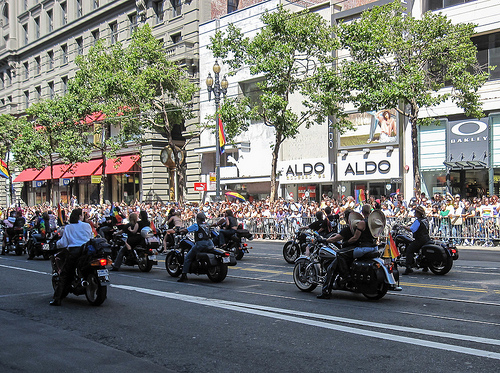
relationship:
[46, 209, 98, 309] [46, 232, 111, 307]
motorcyclist on motorcycle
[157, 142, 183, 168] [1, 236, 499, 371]
clock overlooking street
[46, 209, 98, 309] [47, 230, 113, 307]
motorcyclist riding a bike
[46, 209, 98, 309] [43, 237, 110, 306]
motorcyclist riding motorcycle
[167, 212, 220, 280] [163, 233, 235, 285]
biker riding motorcycle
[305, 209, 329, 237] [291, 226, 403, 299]
person riding motorcycle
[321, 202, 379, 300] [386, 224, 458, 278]
person riding motorcycle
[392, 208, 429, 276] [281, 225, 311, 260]
biker riding motorcycle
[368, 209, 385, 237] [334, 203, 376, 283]
hat behind woman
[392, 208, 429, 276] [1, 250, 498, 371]
biker on street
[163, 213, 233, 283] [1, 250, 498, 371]
motorist on street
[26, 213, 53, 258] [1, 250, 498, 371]
motorist on street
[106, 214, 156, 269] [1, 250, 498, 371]
motorist on street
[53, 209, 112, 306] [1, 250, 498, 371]
motorist on street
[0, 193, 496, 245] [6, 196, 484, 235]
crowd on people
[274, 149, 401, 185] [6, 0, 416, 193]
signs on buildings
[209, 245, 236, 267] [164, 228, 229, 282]
light on bike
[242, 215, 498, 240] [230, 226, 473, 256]
fence by side walk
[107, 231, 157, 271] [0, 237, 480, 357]
motorcycle on street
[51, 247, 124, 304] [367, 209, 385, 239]
bike with hat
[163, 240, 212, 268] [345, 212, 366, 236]
bike with hat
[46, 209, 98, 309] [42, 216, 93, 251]
motorcyclist in a shirt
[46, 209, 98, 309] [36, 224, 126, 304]
motorcyclist on a motorcycle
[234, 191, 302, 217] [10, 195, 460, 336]
spectators watching parade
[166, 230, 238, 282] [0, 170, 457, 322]
motorcyclist in a parade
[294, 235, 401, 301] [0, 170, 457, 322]
motorcyclist in a parade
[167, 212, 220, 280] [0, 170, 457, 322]
biker in a parade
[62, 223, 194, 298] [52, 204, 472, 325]
motorcyclist in a parade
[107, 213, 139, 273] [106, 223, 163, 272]
motorcyclist on a motorcycle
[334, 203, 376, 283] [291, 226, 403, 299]
woman on a motorcycle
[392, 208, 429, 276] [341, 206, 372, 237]
biker wearing hat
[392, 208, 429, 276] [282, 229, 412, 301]
biker on a motorcycle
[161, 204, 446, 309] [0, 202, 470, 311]
people riding motorcycle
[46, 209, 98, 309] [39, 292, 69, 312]
motorcyclist wearing shoes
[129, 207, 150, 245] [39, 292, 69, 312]
woman wearing shoes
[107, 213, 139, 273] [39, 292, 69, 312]
motorcyclist wearing shoes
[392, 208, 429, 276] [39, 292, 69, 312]
biker wearing shoes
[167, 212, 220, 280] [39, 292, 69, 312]
biker wearing shoes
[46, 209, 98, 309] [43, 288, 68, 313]
motorcyclist wearing shoes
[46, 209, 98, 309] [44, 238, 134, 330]
motorcyclist wearing pants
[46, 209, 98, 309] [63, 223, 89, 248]
motorcyclist wearing shirt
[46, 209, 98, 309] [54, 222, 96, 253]
motorcyclist wearing shirt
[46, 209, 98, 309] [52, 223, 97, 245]
motorcyclist wearing shirt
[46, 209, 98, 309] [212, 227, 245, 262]
motorcyclist on motorcycle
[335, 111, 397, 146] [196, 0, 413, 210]
print on building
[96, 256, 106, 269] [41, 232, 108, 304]
light on motorcycle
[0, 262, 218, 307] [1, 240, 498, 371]
line on road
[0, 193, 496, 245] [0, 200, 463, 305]
crowd watches motorcycles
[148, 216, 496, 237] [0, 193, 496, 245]
barriers to keep crowd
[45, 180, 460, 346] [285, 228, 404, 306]
people riding motorcycle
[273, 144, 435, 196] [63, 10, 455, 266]
sign on building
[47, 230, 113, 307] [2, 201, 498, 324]
bike on parade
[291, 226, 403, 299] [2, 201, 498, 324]
motorcycle on parade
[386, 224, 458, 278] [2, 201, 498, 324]
motorcycle on parade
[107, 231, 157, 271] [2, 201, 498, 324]
motorcycle on parade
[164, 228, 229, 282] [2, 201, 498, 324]
bike on parade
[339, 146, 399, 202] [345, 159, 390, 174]
store call aldo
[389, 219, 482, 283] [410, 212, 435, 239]
biker wears vest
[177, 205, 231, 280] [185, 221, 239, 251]
biker wears vest